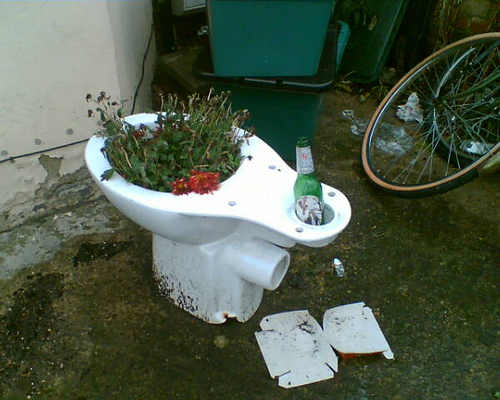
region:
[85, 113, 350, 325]
white toilet sitting on the ground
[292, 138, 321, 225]
empty beer bottle in the toilet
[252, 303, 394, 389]
paper sandwich container on the ground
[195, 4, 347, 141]
two green totes with black lids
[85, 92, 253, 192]
a flowering plant in the toilet bowl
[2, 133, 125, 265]
peeling paint on the bottom of the wall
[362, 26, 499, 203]
bicycle tires on the right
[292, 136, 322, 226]
a green beer bottle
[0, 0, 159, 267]
beige wall on the left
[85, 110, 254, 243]
bowl of the toilet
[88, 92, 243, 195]
flowers and weeds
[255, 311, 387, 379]
a filthy cardboard box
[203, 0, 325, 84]
a large green bin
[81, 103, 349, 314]
a beer bottle in a toilet seat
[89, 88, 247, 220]
weeds growing out of a toilet bowl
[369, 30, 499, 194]
a black bike wheel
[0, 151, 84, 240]
chipping paint on a wall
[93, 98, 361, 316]
a filthy toilet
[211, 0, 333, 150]
a stack of green bins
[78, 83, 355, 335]
A toilet bowl in a yard.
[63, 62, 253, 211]
flowers inside of a toilet bowl.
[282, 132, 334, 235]
a bottle of alcohol in a toilet bowl.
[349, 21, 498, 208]
a large bike tire in a yard.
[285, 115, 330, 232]
a bottle of bear in a toilet bowl.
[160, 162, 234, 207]
red flowers in a toilet bowl.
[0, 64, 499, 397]
a green yard with a bike on it.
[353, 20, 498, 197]
a large bike wheel.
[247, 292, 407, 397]
a piece of trash on the ground.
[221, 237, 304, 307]
an outlet on a toilet bowl.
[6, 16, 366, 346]
toilet placed outside by angled wall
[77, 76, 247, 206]
mostly dried up flowers on green leafy stems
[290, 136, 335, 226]
green bottle with labels in smaller toilet hole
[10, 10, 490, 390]
worn brown and dark green ground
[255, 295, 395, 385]
inside of flattened paper container on ground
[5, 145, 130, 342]
peeled paint on wall over black shapes on ground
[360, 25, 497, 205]
slanted black bicycles wheels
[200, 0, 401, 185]
stacked green plastic containers and lid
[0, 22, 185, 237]
black wires along edge of wall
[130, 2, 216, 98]
dark space between wall and containers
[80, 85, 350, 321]
An old toilet with flowers inside of the bowl.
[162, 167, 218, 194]
Red flowers lying against the toilet rim.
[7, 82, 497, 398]
The tiolet is sitting on a dirt ground.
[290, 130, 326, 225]
Green bottle inside of a hole on the toilet.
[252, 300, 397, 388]
An old cardboard container on the ground.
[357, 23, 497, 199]
A bicycle wheel near the toilet.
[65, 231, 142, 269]
A hole at the base of the wall.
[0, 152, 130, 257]
Peeling paint on the wall.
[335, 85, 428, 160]
Trash on the ground near the bike tire.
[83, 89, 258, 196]
Flower stems and leaves inside of the toilet bowl.